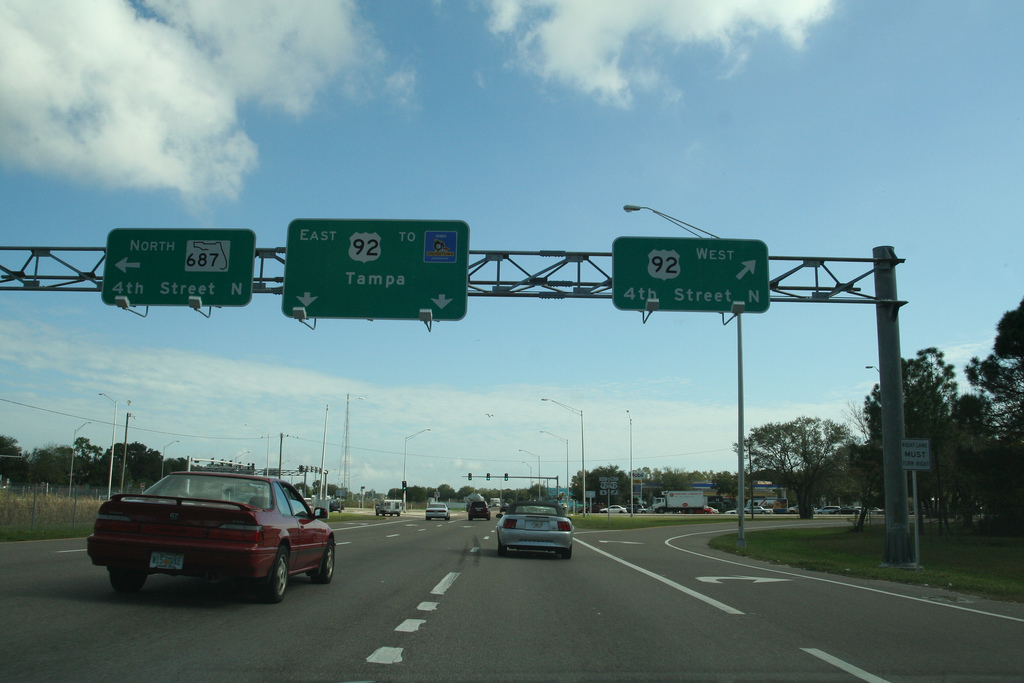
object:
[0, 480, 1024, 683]
multilanehighway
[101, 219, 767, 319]
signs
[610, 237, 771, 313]
sign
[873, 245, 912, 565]
pole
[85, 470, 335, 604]
car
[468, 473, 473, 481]
light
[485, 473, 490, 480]
light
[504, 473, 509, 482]
light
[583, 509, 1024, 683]
lane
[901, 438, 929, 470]
sign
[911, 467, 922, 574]
pole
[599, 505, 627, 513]
vehicle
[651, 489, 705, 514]
vehicle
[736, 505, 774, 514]
vehicle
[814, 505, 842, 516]
vehicle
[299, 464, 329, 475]
light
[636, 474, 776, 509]
gas station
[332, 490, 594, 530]
intersection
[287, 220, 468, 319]
sign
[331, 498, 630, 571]
distance